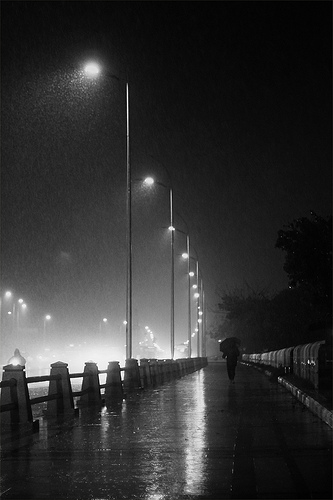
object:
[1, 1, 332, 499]
photo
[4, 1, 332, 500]
nighttime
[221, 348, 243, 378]
person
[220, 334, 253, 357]
umbrella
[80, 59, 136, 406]
streelamp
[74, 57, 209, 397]
row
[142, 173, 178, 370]
streelamp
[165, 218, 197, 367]
streelamp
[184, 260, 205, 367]
streelamp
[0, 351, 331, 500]
sidewalk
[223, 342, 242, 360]
hood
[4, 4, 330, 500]
dark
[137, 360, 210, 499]
light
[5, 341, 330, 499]
street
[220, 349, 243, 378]
coat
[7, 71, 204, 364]
mist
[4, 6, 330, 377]
air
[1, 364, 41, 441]
column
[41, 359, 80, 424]
column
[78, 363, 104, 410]
column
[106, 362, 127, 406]
column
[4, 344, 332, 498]
bridge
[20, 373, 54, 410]
pole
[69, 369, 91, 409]
pole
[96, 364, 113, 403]
pole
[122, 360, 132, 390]
pole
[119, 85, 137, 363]
metal pole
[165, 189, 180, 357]
metal pole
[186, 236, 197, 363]
metal pole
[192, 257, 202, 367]
metal pole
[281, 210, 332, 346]
tree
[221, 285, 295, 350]
tree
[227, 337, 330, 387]
cement riser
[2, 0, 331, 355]
sky